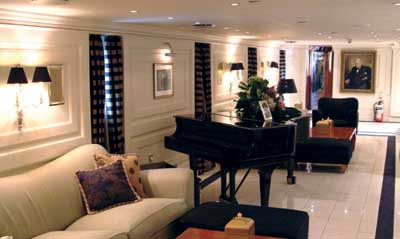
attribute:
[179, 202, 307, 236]
coffee table — black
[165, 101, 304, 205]
piano — baby grand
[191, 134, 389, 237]
floors — shiny